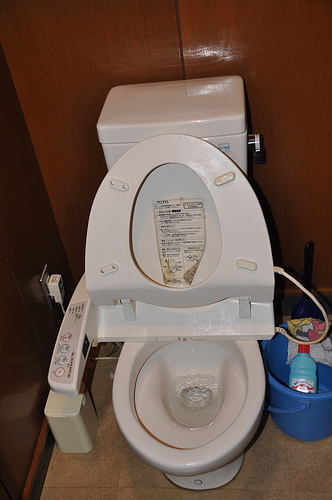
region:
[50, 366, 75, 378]
a sign is written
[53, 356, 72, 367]
a sign is written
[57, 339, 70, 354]
a sign is written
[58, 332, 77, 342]
a sign is written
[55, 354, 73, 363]
a sign is written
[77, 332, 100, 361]
a sign is written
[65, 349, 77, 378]
black writing on toilet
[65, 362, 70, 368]
black writing on toilet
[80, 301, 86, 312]
black writing on toilet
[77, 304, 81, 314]
black writing on toilet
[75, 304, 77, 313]
black writing on toilet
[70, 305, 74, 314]
black writing on toilet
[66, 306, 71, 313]
black writing on toilet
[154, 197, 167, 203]
black writing on toilet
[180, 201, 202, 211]
black writing on toilet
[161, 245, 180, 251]
black writing on toilet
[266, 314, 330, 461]
A blue bucket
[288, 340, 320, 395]
The blue bottle in the bucket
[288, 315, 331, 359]
The rag that is over the bucket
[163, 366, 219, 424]
The water in the toilet is clear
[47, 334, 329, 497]
The floor is clean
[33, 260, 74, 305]
The toilet is plugged in the socket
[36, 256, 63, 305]
The socket is silver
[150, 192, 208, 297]
The white sticker on the toilet lid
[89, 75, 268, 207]
The tank is white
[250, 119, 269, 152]
The knob on the tank is silver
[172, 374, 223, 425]
the water in the toilet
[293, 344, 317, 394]
the blue bollte in the bucket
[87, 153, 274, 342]
the toilet seat is up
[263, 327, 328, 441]
the bucket is dark blue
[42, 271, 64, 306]
the plug for the toilet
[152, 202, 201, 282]
the paper coming off the seat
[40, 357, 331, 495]
the floor is beige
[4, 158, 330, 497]
the walls are dark brown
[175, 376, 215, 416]
the water is moving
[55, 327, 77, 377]
buttons on the arm rest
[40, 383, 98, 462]
the bin is white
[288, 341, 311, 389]
the bottle is blue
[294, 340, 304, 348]
the cap is red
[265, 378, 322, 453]
the bucket on the floor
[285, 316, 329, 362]
the towel on the bucket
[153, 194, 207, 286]
the sticker is peeling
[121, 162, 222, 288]
sticker on the lid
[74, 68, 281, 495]
white porcelain toilet fixture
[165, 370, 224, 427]
clear water in toilet bowl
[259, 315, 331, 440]
blue pail on floor near toilet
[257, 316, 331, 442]
blue plastic pail on floor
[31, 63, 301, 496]
a white toilet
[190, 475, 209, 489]
a round white button on toilet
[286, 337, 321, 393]
a blue and red bottle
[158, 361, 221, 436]
water in the toilet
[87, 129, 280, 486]
the lid is raised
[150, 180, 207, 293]
a paper on the toilet